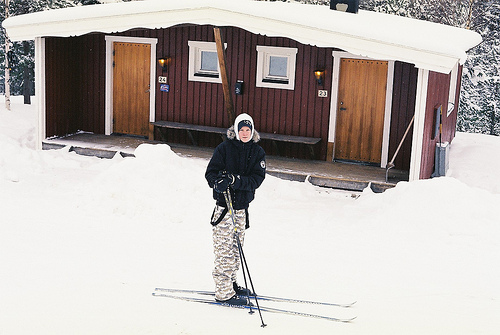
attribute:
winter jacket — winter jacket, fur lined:
[182, 117, 276, 214]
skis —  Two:
[152, 281, 357, 322]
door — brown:
[111, 36, 153, 143]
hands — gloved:
[214, 172, 239, 189]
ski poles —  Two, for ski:
[223, 190, 270, 328]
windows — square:
[182, 26, 335, 113]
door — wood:
[336, 55, 387, 167]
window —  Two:
[257, 47, 301, 91]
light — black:
[309, 70, 323, 81]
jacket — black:
[221, 137, 264, 188]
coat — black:
[143, 129, 350, 236]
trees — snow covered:
[0, 2, 498, 133]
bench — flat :
[156, 118, 320, 158]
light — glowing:
[310, 65, 324, 82]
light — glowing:
[156, 51, 169, 70]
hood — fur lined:
[225, 109, 264, 146]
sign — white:
[156, 74, 166, 84]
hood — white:
[231, 110, 257, 145]